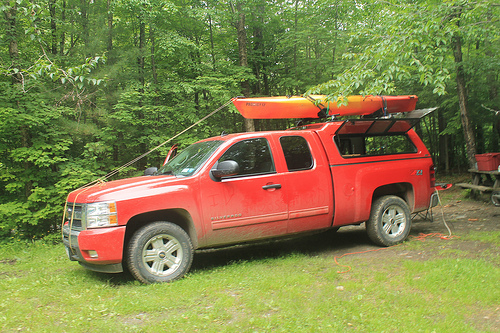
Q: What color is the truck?
A: Red.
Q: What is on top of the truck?
A: A kayak.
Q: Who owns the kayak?
A: Same person who owns the truck.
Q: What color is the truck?
A: Red.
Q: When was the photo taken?
A: On a camping trip.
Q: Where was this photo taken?
A: In the woods.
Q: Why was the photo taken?
A: So someone could show the fun they're going to have.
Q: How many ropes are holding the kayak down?
A: 2.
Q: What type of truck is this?
A: Z71 Silverado.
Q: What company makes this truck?
A: Chevrolet.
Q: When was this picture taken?
A: Daytime.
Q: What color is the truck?
A: Red.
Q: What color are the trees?
A: Green.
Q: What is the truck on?
A: Grass.